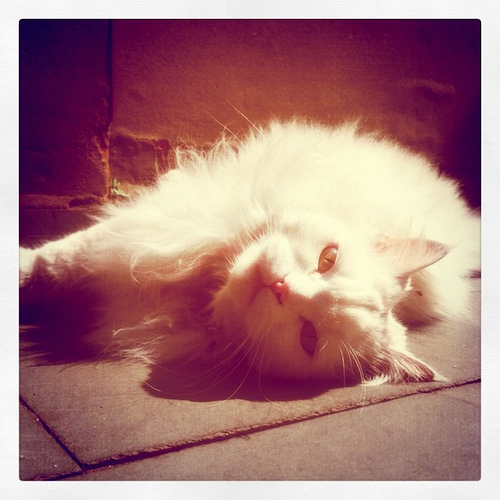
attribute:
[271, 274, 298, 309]
nose — pink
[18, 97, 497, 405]
cat — fluffy, white, lying down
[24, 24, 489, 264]
wall — white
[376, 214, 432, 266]
hairs — white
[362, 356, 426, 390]
hairs — white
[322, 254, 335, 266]
slit — black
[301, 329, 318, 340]
slit — black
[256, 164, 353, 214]
fur — white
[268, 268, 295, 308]
nose — pink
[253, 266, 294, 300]
nose — pink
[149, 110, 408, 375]
cat — white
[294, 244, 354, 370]
eyes — big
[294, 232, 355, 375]
eyes — brown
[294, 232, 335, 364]
cat — eyes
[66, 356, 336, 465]
ground — shadow 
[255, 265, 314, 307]
cat — nose 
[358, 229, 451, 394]
cat — ears 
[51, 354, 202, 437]
cat — mat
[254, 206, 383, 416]
cat — whiskers 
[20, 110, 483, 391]
cat — white, rug white, laying, not sleeping, posing, laying on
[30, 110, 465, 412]
cat — white fluffy , white 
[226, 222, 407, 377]
face — white fluffy cats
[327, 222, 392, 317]
hair — cats , sticking out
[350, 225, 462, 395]
ears — cats , perked up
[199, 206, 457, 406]
head — turned sideways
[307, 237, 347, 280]
eye — yellow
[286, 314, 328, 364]
eye — yellow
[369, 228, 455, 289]
ear — pointy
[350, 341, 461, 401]
ear — pointy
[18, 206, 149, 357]
legs — white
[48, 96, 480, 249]
fur — white, fluffy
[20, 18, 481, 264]
background — brown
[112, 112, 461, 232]
fur — fuzzy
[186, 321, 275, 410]
whiskers — white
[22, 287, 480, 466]
rug — brown